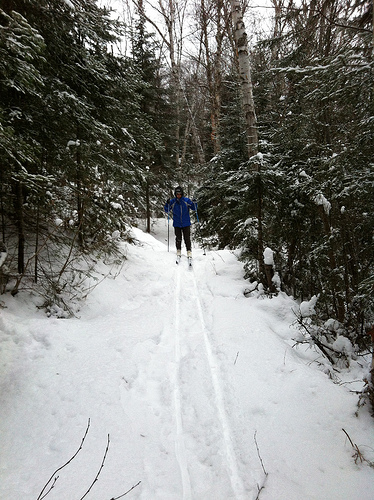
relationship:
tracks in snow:
[110, 332, 154, 375] [174, 430, 193, 455]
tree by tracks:
[70, 92, 105, 147] [110, 332, 154, 375]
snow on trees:
[174, 430, 193, 455] [124, 74, 171, 124]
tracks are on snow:
[110, 332, 154, 375] [174, 430, 193, 455]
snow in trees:
[174, 430, 193, 455] [124, 74, 171, 124]